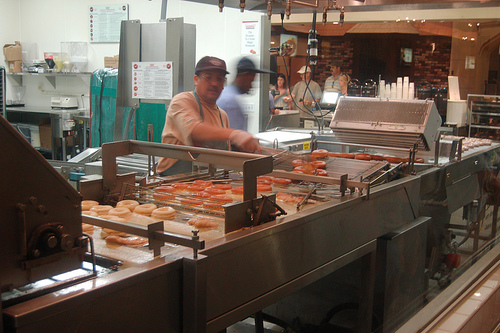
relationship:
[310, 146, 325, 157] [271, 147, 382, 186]
doughnuts on top of tray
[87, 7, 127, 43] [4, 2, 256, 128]
sign on top of wall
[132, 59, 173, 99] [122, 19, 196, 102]
sign on top of equipment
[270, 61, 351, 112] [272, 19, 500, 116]
customer inside background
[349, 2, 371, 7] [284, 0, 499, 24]
lights on top of ceiling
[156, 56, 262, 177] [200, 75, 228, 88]
conveyor has glasses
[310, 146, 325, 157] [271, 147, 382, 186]
doughnuts on top of belt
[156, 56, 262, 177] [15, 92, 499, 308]
conveyor behind conveyor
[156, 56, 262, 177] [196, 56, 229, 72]
conveyor wearing hat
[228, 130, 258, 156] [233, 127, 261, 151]
hand covered with glove